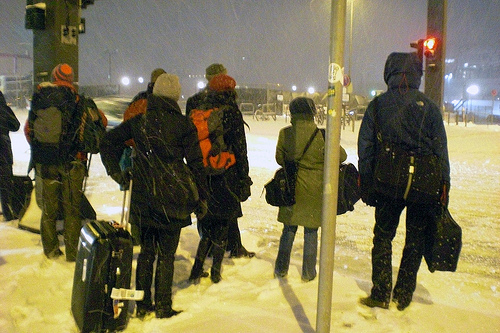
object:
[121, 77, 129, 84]
light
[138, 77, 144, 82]
light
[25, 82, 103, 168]
jackets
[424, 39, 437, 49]
light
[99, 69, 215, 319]
woman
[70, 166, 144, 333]
suitcase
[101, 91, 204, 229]
coat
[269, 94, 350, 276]
woman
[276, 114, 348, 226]
coat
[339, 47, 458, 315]
man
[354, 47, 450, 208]
coat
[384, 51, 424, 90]
hood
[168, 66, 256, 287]
woman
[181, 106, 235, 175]
backpack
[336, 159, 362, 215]
backpack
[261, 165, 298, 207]
handbag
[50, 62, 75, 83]
cap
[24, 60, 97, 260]
man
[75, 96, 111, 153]
backpack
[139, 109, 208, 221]
handbag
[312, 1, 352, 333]
pole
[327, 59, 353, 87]
sticker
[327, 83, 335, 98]
sticker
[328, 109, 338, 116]
sticker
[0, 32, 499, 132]
background